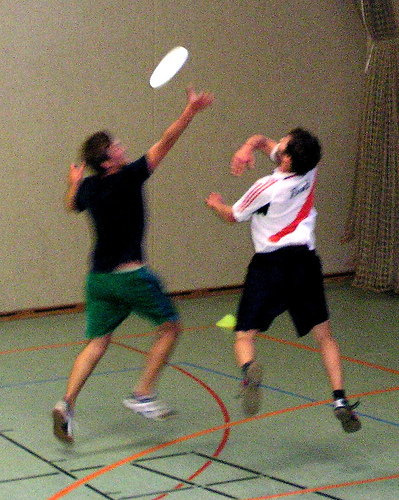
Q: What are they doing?
A: Playing frisbee.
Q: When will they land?
A: After catching the frisbee.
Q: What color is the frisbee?
A: White.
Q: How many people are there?
A: 2.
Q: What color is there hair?
A: Brown.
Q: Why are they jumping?
A: To catch the frisbee.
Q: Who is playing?
A: Two men.